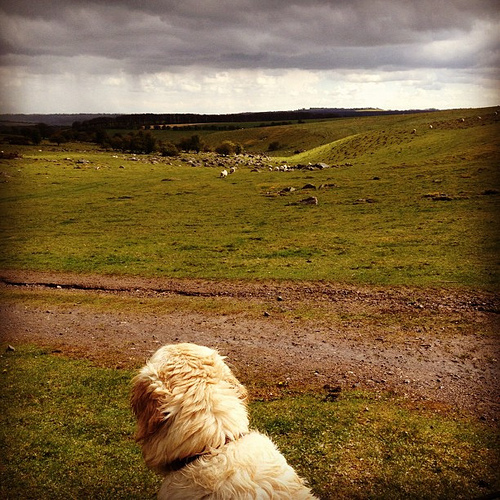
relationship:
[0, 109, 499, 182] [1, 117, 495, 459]
animal grazing in field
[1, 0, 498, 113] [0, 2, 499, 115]
sky with clouds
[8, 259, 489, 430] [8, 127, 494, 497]
path in field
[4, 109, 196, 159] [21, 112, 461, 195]
trees in distance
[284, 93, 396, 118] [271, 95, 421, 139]
plateau on top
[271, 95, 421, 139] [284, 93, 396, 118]
top of plateau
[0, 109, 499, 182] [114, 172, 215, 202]
animal in field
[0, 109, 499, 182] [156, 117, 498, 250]
animal grazing down hill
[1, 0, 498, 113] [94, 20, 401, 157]
sky with a lot clouds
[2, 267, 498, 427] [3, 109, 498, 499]
dirt with grass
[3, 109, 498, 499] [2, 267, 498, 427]
grass with dirt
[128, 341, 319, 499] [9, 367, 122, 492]
dog sitting on grass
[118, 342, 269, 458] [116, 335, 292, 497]
head on dog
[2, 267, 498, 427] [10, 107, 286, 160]
dirt in forest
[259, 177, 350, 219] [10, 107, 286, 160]
stones in forest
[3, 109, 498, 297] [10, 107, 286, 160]
grass in forest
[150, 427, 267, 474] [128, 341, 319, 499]
collar on dog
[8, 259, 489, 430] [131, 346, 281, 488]
path in front of dog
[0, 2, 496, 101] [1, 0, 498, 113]
clouds in sky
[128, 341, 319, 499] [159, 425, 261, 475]
dog with collar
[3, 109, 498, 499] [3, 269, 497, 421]
grass by road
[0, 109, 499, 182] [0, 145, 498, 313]
animal in meadow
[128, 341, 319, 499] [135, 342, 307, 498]
dog has fur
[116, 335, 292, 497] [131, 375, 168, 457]
dog has ears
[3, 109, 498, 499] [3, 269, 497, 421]
grass across road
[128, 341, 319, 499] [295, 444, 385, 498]
dog on grass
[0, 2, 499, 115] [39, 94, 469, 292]
clouds close to land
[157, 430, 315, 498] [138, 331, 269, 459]
back of dog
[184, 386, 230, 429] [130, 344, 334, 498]
fur of dog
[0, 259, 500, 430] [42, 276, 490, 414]
path in front of dog